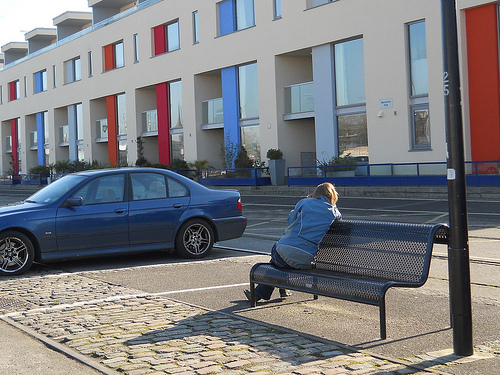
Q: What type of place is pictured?
A: It is a parking lot.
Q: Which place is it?
A: It is a parking lot.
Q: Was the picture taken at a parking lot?
A: Yes, it was taken in a parking lot.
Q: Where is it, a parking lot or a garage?
A: It is a parking lot.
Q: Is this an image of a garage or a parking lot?
A: It is showing a parking lot.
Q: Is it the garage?
A: No, it is the parking lot.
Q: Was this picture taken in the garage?
A: No, the picture was taken in the parking lot.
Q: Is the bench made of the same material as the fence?
A: Yes, both the bench and the fence are made of metal.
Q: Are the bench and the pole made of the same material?
A: Yes, both the bench and the pole are made of metal.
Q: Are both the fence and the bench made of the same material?
A: Yes, both the fence and the bench are made of metal.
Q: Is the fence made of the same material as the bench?
A: Yes, both the fence and the bench are made of metal.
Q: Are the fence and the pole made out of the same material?
A: Yes, both the fence and the pole are made of metal.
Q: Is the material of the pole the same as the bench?
A: Yes, both the pole and the bench are made of metal.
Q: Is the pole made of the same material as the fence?
A: Yes, both the pole and the fence are made of metal.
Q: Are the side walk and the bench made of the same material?
A: No, the side walk is made of concrete and the bench is made of metal.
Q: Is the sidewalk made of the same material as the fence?
A: No, the sidewalk is made of cement and the fence is made of metal.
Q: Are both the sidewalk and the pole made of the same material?
A: No, the sidewalk is made of concrete and the pole is made of metal.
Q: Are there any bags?
A: No, there are no bags.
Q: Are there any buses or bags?
A: No, there are no bags or buses.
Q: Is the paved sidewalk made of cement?
A: Yes, the side walk is made of cement.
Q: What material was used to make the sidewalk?
A: The sidewalk is made of cement.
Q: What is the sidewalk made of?
A: The sidewalk is made of concrete.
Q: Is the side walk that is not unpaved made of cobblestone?
A: No, the sidewalk is made of cement.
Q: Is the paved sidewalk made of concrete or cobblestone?
A: The sidewalk is made of concrete.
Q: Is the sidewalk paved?
A: Yes, the sidewalk is paved.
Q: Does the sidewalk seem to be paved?
A: Yes, the sidewalk is paved.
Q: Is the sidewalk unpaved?
A: No, the sidewalk is paved.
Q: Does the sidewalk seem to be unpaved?
A: No, the sidewalk is paved.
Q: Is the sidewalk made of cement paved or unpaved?
A: The sidewalk is paved.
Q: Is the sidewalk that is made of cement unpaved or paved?
A: The sidewalk is paved.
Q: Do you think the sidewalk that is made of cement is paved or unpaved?
A: The sidewalk is paved.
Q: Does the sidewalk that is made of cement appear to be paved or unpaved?
A: The sidewalk is paved.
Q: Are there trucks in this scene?
A: No, there are no trucks.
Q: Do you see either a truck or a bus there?
A: No, there are no trucks or buses.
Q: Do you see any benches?
A: Yes, there is a bench.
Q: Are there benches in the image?
A: Yes, there is a bench.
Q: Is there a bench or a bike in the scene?
A: Yes, there is a bench.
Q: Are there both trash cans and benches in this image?
A: No, there is a bench but no trash cans.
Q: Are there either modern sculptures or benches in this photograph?
A: Yes, there is a modern bench.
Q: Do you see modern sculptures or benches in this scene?
A: Yes, there is a modern bench.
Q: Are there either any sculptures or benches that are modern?
A: Yes, the bench is modern.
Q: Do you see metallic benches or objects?
A: Yes, there is a metal bench.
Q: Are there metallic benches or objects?
A: Yes, there is a metal bench.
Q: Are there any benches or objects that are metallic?
A: Yes, the bench is metallic.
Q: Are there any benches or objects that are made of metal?
A: Yes, the bench is made of metal.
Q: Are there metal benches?
A: Yes, there is a metal bench.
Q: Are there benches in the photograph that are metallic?
A: Yes, there is a bench that is metallic.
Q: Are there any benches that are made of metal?
A: Yes, there is a bench that is made of metal.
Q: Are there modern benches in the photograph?
A: Yes, there is a modern bench.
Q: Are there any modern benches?
A: Yes, there is a modern bench.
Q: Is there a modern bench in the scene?
A: Yes, there is a modern bench.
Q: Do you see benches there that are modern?
A: Yes, there is a modern bench.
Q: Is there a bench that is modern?
A: Yes, there is a bench that is modern.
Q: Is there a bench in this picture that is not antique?
A: Yes, there is an modern bench.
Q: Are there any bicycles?
A: No, there are no bicycles.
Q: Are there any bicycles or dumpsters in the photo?
A: No, there are no bicycles or dumpsters.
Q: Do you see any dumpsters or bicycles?
A: No, there are no bicycles or dumpsters.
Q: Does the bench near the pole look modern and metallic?
A: Yes, the bench is modern and metallic.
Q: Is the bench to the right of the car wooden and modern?
A: No, the bench is modern but metallic.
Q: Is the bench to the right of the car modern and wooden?
A: No, the bench is modern but metallic.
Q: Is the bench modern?
A: Yes, the bench is modern.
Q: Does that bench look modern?
A: Yes, the bench is modern.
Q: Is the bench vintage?
A: No, the bench is modern.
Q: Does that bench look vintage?
A: No, the bench is modern.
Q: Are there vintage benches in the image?
A: No, there is a bench but it is modern.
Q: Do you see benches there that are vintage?
A: No, there is a bench but it is modern.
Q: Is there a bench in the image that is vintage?
A: No, there is a bench but it is modern.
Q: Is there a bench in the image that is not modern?
A: No, there is a bench but it is modern.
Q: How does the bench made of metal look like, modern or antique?
A: The bench is modern.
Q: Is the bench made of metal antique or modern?
A: The bench is modern.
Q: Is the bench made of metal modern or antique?
A: The bench is modern.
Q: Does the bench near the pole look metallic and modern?
A: Yes, the bench is metallic and modern.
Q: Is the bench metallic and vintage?
A: No, the bench is metallic but modern.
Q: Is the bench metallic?
A: Yes, the bench is metallic.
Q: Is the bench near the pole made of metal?
A: Yes, the bench is made of metal.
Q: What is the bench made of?
A: The bench is made of metal.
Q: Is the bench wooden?
A: No, the bench is metallic.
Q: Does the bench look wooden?
A: No, the bench is metallic.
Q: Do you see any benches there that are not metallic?
A: No, there is a bench but it is metallic.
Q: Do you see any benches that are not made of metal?
A: No, there is a bench but it is made of metal.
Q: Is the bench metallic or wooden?
A: The bench is metallic.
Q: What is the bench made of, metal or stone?
A: The bench is made of metal.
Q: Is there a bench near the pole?
A: Yes, there is a bench near the pole.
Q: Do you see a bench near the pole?
A: Yes, there is a bench near the pole.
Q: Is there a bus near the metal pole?
A: No, there is a bench near the pole.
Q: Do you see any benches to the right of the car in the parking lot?
A: Yes, there is a bench to the right of the car.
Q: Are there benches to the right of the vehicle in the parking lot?
A: Yes, there is a bench to the right of the car.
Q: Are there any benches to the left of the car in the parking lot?
A: No, the bench is to the right of the car.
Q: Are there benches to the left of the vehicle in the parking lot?
A: No, the bench is to the right of the car.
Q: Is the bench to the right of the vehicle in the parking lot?
A: Yes, the bench is to the right of the car.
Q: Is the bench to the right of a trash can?
A: No, the bench is to the right of the car.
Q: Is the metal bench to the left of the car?
A: No, the bench is to the right of the car.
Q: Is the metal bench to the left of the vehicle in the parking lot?
A: No, the bench is to the right of the car.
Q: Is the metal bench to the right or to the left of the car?
A: The bench is to the right of the car.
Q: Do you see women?
A: Yes, there is a woman.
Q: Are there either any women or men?
A: Yes, there is a woman.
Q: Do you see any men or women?
A: Yes, there is a woman.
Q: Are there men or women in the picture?
A: Yes, there is a woman.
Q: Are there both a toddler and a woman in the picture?
A: No, there is a woman but no toddlers.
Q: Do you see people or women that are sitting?
A: Yes, the woman is sitting.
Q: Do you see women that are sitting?
A: Yes, there is a woman that is sitting.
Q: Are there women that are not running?
A: Yes, there is a woman that is sitting.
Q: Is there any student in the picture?
A: No, there are no students.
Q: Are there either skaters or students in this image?
A: No, there are no students or skaters.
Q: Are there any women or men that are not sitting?
A: No, there is a woman but she is sitting.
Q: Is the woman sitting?
A: Yes, the woman is sitting.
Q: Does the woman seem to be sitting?
A: Yes, the woman is sitting.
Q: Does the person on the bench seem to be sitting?
A: Yes, the woman is sitting.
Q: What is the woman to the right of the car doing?
A: The woman is sitting.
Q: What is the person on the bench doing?
A: The woman is sitting.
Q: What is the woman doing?
A: The woman is sitting.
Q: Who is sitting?
A: The woman is sitting.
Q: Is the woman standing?
A: No, the woman is sitting.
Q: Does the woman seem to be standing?
A: No, the woman is sitting.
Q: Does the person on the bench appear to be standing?
A: No, the woman is sitting.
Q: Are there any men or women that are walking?
A: No, there is a woman but she is sitting.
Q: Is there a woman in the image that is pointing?
A: No, there is a woman but she is sitting.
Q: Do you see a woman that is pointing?
A: No, there is a woman but she is sitting.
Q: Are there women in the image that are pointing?
A: No, there is a woman but she is sitting.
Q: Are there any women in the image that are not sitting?
A: No, there is a woman but she is sitting.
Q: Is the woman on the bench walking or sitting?
A: The woman is sitting.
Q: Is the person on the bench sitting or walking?
A: The woman is sitting.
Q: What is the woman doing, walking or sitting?
A: The woman is sitting.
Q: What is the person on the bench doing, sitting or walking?
A: The woman is sitting.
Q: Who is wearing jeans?
A: The woman is wearing jeans.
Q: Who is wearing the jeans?
A: The woman is wearing jeans.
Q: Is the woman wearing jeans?
A: Yes, the woman is wearing jeans.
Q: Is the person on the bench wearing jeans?
A: Yes, the woman is wearing jeans.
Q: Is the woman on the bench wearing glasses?
A: No, the woman is wearing jeans.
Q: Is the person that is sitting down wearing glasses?
A: No, the woman is wearing jeans.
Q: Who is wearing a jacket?
A: The woman is wearing a jacket.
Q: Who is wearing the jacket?
A: The woman is wearing a jacket.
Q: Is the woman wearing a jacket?
A: Yes, the woman is wearing a jacket.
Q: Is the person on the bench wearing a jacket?
A: Yes, the woman is wearing a jacket.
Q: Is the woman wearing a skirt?
A: No, the woman is wearing a jacket.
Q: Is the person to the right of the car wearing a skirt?
A: No, the woman is wearing a jacket.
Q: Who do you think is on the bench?
A: The woman is on the bench.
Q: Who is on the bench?
A: The woman is on the bench.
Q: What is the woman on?
A: The woman is on the bench.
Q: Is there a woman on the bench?
A: Yes, there is a woman on the bench.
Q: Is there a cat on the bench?
A: No, there is a woman on the bench.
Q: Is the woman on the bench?
A: Yes, the woman is on the bench.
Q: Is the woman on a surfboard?
A: No, the woman is on the bench.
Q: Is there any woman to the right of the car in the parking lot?
A: Yes, there is a woman to the right of the car.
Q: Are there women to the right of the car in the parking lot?
A: Yes, there is a woman to the right of the car.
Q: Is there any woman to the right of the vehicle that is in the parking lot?
A: Yes, there is a woman to the right of the car.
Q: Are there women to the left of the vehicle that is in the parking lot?
A: No, the woman is to the right of the car.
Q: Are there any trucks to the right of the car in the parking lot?
A: No, there is a woman to the right of the car.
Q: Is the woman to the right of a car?
A: Yes, the woman is to the right of a car.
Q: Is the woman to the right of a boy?
A: No, the woman is to the right of a car.